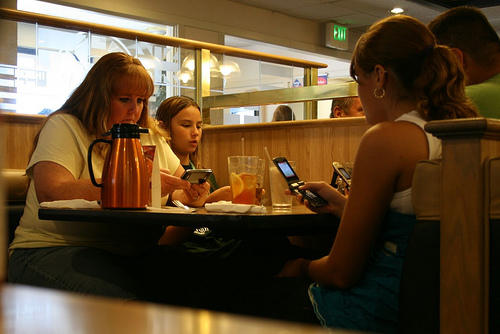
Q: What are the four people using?
A: Phones.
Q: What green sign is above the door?
A: Exit.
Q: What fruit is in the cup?
A: Orange.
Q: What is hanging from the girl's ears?
A: Earrings.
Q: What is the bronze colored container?
A: Coffee.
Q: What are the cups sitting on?
A: Table.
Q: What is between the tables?
A: A glass partition.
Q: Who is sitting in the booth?
A: A family of four.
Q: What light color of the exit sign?
A: Green.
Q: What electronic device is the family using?
A: Cell phone.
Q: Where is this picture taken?
A: A restaurant.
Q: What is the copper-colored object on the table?
A: A coffee carafe.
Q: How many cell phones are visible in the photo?
A: Three.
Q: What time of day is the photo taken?
A: Daytime.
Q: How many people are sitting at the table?
A: Four.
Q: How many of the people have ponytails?
A: One.